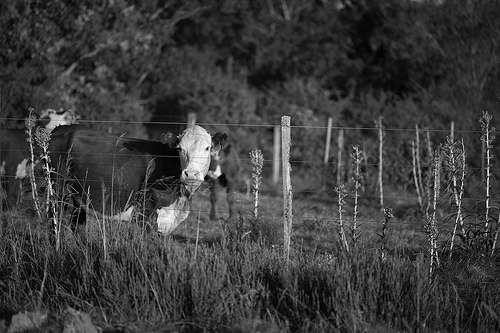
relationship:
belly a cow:
[70, 193, 137, 225] [43, 95, 250, 267]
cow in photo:
[45, 124, 227, 233] [9, 6, 494, 325]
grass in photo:
[238, 257, 338, 325] [9, 6, 494, 325]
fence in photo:
[6, 94, 492, 279] [9, 6, 494, 325]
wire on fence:
[241, 114, 347, 198] [235, 112, 394, 274]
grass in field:
[208, 246, 308, 297] [103, 213, 374, 304]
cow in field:
[45, 124, 227, 233] [69, 194, 382, 322]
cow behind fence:
[45, 124, 227, 233] [149, 115, 341, 225]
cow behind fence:
[45, 124, 227, 233] [147, 120, 279, 252]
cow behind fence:
[45, 124, 227, 233] [130, 129, 240, 257]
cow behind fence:
[45, 124, 227, 233] [124, 118, 224, 251]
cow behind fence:
[45, 124, 227, 233] [98, 117, 213, 229]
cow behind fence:
[45, 124, 227, 233] [122, 125, 205, 223]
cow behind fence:
[45, 124, 227, 233] [97, 117, 218, 256]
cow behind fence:
[45, 124, 227, 233] [138, 120, 208, 260]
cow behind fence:
[45, 124, 227, 233] [178, 103, 243, 264]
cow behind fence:
[45, 154, 251, 233] [15, 118, 482, 278]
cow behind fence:
[45, 124, 227, 233] [17, 120, 493, 233]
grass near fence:
[30, 177, 490, 329] [14, 143, 492, 258]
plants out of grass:
[94, 190, 140, 259] [42, 173, 490, 319]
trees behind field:
[36, 62, 154, 189] [8, 103, 490, 333]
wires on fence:
[33, 108, 282, 268] [6, 109, 488, 333]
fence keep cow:
[6, 94, 492, 279] [26, 126, 236, 277]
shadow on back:
[122, 123, 182, 166] [56, 121, 176, 154]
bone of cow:
[66, 118, 77, 151] [30, 118, 232, 260]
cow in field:
[45, 124, 227, 233] [21, 162, 494, 333]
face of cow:
[173, 125, 223, 185] [35, 112, 218, 258]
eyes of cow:
[174, 138, 212, 151] [57, 113, 224, 243]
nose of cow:
[183, 167, 214, 178] [50, 104, 229, 281]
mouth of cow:
[174, 175, 204, 189] [25, 100, 235, 274]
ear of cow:
[202, 130, 233, 159] [51, 110, 243, 252]